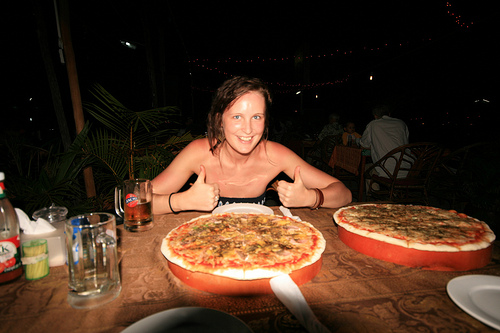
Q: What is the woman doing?
A: Drinking beer.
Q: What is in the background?
A: A dark restaurant.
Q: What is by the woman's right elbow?
A: A mug of beer.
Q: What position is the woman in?
A: Sitting with her arms on the table.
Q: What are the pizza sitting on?
A: A wooden table.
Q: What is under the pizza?
A: A red tray.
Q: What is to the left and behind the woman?
A: A green plant.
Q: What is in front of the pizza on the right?
A: A white plate.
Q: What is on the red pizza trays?
A: Pizza.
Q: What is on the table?
A: Food.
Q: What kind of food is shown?
A: Pizza.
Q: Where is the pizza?
A: On trays.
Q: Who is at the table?
A: A woman.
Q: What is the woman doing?
A: Posing.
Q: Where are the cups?
A: On the table.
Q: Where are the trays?
A: On the table.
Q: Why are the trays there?
A: To hold the pizza.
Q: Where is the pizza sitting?
A: On the table.